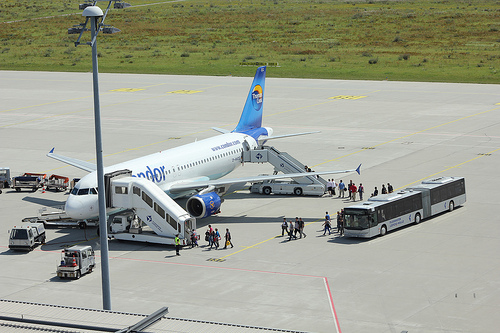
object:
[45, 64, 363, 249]
plane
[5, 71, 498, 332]
runway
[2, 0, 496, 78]
grass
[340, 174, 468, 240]
bus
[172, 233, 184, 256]
director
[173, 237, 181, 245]
vest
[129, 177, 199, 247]
stairs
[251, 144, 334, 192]
stairs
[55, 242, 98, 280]
truck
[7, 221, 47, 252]
truck